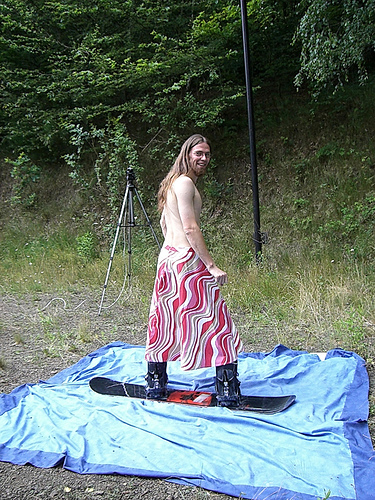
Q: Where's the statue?
A: On top of the building.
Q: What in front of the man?
A: Trees.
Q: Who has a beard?
A: The man.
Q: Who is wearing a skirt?
A: A man.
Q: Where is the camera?
A: On the tripod.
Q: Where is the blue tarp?
A: Under the man.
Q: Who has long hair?
A: The man.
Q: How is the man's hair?
A: Long.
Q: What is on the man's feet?
A: A snowboard.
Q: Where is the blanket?
A: On the ground.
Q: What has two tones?
A: The blanket.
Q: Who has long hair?
A: The man.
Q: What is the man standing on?
A: A snowboard.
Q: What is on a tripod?
A: A camera.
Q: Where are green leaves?
A: On trees.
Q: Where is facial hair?
A: On man's face.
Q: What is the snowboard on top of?
A: A blue blanket.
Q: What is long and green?
A: Grass.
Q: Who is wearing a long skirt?
A: A man.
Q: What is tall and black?
A: A pole.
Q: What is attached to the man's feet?
A: A snowboard.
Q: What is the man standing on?
A: A blue blanket.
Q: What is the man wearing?
A: A red, pink, grey and white skirt.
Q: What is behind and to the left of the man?
A: A camera tripod.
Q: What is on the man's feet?
A: Ski boots.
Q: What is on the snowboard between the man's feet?
A: A red design.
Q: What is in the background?
A: Trees.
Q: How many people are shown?
A: One.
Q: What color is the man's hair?
A: Brown.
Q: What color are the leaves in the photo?
A: Green.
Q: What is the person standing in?
A: A snowboard.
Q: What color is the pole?
A: Black.